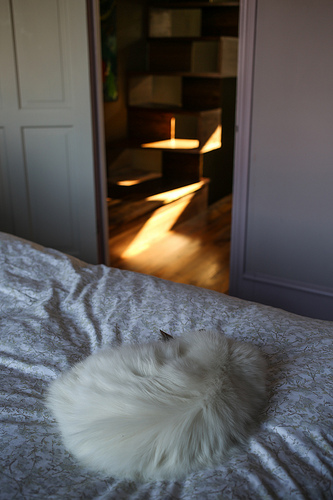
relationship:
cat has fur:
[45, 328, 273, 485] [46, 330, 272, 488]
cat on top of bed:
[45, 328, 273, 485] [0, 231, 332, 500]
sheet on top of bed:
[1, 232, 332, 499] [0, 231, 332, 500]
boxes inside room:
[107, 1, 239, 206] [100, 1, 240, 294]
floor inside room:
[108, 194, 232, 299] [100, 1, 240, 294]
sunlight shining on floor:
[127, 225, 228, 289] [108, 194, 232, 299]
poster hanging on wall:
[102, 3, 117, 102] [100, 0, 148, 144]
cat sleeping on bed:
[45, 328, 273, 485] [0, 231, 332, 500]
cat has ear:
[45, 328, 273, 485] [160, 330, 173, 342]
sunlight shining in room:
[127, 225, 228, 289] [100, 1, 240, 294]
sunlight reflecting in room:
[127, 225, 228, 289] [100, 1, 240, 294]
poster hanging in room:
[102, 3, 117, 102] [100, 1, 240, 294]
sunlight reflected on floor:
[127, 225, 228, 289] [108, 194, 232, 299]